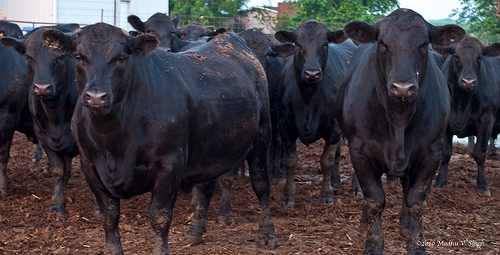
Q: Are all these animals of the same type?
A: Yes, all the animals are cows.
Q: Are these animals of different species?
A: No, all the animals are cows.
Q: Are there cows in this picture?
A: Yes, there are cows.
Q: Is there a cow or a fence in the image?
A: Yes, there are cows.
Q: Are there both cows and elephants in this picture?
A: No, there are cows but no elephants.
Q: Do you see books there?
A: No, there are no books.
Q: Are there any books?
A: No, there are no books.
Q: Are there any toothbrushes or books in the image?
A: No, there are no books or toothbrushes.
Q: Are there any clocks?
A: No, there are no clocks.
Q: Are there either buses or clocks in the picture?
A: No, there are no clocks or buses.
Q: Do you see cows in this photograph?
A: Yes, there is a cow.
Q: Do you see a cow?
A: Yes, there is a cow.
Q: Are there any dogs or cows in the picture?
A: Yes, there is a cow.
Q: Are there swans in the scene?
A: No, there are no swans.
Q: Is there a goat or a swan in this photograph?
A: No, there are no swans or goats.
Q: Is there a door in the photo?
A: Yes, there is a door.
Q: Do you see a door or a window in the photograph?
A: Yes, there is a door.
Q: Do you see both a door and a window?
A: No, there is a door but no windows.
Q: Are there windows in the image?
A: No, there are no windows.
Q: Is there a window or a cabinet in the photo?
A: No, there are no windows or cabinets.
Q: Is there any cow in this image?
A: Yes, there is a cow.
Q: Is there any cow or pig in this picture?
A: Yes, there is a cow.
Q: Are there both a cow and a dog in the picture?
A: No, there is a cow but no dogs.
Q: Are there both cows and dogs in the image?
A: No, there is a cow but no dogs.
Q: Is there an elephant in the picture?
A: No, there are no elephants.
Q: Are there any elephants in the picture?
A: No, there are no elephants.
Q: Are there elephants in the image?
A: No, there are no elephants.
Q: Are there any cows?
A: Yes, there is a cow.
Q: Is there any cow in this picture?
A: Yes, there is a cow.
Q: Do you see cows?
A: Yes, there is a cow.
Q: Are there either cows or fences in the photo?
A: Yes, there is a cow.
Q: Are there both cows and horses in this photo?
A: No, there is a cow but no horses.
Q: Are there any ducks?
A: No, there are no ducks.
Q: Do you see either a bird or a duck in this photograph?
A: No, there are no ducks or birds.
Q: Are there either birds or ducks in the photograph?
A: No, there are no ducks or birds.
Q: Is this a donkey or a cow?
A: This is a cow.